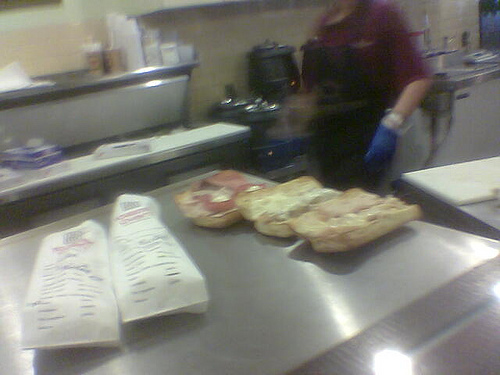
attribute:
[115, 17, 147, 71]
containers — stack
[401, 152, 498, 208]
cutting board — white, plastic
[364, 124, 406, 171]
glove — blue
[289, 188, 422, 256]
bread — halved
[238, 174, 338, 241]
bread — halved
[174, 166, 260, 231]
bread — halved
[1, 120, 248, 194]
area — food preparation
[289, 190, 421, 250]
bread — halved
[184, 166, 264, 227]
bread — halved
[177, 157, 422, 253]
bread — french, toasted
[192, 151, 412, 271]
bread — french, halved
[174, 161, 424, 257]
sandwiches — three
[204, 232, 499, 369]
steel — stainless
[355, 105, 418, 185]
glove — blue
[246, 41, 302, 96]
pot — large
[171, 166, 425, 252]
breads — toasted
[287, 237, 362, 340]
light — long, reflecting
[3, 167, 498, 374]
table — top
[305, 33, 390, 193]
apron — black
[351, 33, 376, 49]
logo — white